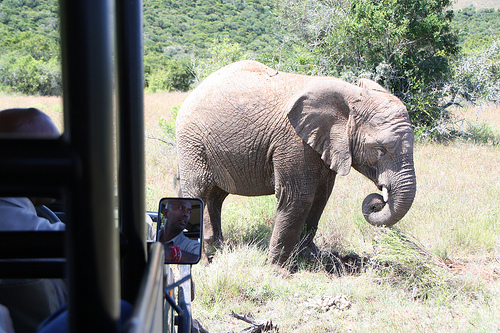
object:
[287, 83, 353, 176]
ear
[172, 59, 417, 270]
elephant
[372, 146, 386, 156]
eye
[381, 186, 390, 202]
tusk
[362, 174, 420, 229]
trunk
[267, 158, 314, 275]
leg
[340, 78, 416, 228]
head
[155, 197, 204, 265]
mirror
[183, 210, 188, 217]
nose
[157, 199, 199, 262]
person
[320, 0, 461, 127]
tree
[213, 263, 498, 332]
grass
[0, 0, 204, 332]
vehicle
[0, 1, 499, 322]
background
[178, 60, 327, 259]
skin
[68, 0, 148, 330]
bars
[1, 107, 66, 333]
man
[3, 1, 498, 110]
foliage